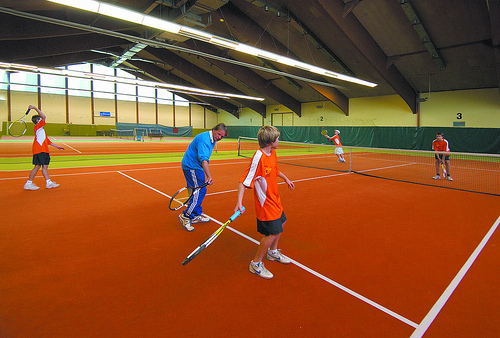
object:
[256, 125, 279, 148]
hair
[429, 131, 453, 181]
person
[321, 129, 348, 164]
player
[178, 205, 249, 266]
bat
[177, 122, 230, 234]
man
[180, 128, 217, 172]
blue shirt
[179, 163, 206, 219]
pants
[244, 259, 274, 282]
shoes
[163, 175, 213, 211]
tennis racket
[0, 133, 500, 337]
court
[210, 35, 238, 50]
lights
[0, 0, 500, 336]
buildings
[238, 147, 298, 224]
shirt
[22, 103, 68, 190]
girl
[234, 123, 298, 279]
boy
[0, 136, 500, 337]
ground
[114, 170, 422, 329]
white line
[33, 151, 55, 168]
shorts